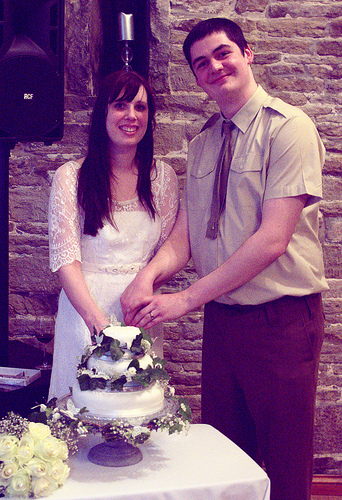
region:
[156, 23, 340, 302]
this is a man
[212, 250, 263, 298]
the man is light skinned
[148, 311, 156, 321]
this is a ring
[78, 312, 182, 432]
this is a cake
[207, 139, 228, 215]
this is a neck tie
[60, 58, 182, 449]
this is a lady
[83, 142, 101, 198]
this is the hair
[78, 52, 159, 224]
woman with brown hair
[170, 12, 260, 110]
man with brown hair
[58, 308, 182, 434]
people cutting a wedding cake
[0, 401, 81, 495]
flowers from a wedding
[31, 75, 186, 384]
woman wearing white dress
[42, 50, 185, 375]
woman wearing wedding dress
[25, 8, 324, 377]
couple cutting wedding cake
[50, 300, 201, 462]
wedding cake with flowers on it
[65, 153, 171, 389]
girl has white dress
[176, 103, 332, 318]
man has brown shirt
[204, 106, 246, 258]
man has brown tie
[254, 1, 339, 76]
grey stones in wall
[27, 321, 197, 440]
white cake on platter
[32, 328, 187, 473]
cake on white table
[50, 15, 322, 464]
a bride and groom cutting a wedding cake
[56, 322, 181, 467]
a small wedding cake on a cake stand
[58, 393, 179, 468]
a cake stand on a table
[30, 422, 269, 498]
table with white tablecloth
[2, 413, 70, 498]
bouquet of white roses on table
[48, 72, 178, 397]
woman in a white wedding dress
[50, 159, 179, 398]
a white wedding dress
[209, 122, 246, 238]
groom's very short necktie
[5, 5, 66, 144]
black speaker on the left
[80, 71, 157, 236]
bride's long brown hair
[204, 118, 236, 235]
The tie the guy is wearing.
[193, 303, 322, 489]
The pants the guy is wearing.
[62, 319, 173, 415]
The cake on the stand.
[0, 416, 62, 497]
The roses on the table.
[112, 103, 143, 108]
The eyes of the girl.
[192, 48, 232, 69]
The eyes of the guy.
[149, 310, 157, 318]
The ring on the guy's finger.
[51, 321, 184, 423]
The butterflies on the cake.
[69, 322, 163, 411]
The flowers on the cake.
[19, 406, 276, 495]
The white table cloth on the table.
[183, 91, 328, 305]
a man's short sleeve shirt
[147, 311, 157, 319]
a man's wedding ring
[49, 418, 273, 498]
a white tablecloth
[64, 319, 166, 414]
a small three tier cake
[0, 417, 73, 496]
a bouquet of white flowers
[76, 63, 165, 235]
a woman's long dark hair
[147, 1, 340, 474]
a stone wall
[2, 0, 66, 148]
a black speaker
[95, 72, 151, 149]
head of a woman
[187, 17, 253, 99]
head of a man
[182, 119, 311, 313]
arm of a man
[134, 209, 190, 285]
arm of a man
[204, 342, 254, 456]
leg of a man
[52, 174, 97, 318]
arm of a woman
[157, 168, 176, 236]
arm of a woman